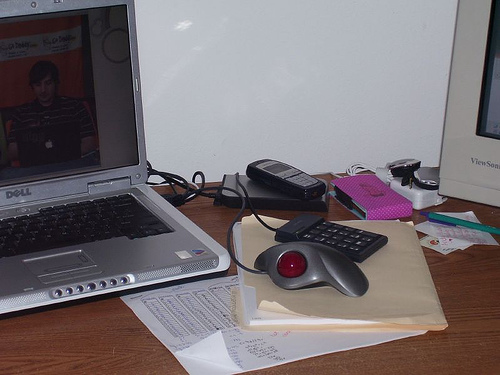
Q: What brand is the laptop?
A: Dell.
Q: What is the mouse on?
A: Manilla folder.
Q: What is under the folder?
A: Paper with writing.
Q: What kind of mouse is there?
A: Track ball.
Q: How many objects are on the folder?
A: Two.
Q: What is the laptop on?
A: Desk.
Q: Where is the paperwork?
A: On the desk.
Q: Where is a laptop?
A: On a desk.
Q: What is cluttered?
A: The desk.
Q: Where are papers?
A: On the desk.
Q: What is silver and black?
A: Laptop.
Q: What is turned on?
A: Computer screen.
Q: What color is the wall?
A: White.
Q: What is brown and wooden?
A: Desk.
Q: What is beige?
A: Folder.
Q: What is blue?
A: A pen.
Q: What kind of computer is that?
A: A dell.